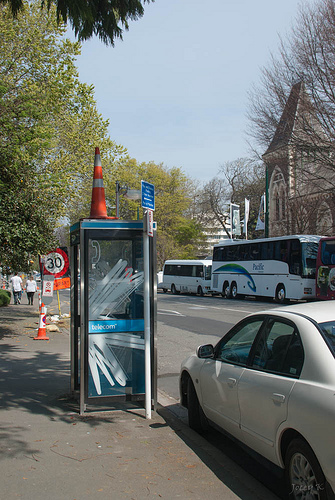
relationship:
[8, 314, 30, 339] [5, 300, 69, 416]
leaves on top of pavement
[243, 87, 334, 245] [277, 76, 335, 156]
building has steeple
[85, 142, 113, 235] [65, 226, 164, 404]
cone on top of telephone booth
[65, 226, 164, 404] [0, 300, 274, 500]
telephone booth on pavement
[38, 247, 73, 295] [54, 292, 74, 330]
signs on pole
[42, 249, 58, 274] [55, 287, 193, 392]
speed limit sign on road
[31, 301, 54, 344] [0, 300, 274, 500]
cone on pavement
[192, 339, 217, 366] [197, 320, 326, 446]
mirror on car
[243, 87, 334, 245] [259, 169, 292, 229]
building has windows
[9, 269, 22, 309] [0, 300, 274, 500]
man walking on pavement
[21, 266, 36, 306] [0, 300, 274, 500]
woman walking on pavement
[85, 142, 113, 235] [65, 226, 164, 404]
cone next to telephone booth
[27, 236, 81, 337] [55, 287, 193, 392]
traffic signs on road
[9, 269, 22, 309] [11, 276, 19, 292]
man wearing shirt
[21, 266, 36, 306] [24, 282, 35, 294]
woman wearing tee shirt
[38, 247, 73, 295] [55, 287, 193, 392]
signs on side of road